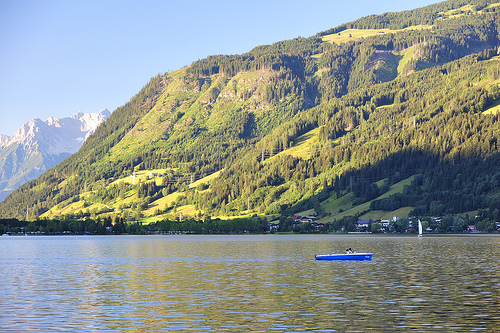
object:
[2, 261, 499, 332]
water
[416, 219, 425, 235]
sail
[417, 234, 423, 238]
boat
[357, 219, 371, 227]
house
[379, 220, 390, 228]
house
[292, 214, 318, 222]
house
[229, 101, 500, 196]
mountain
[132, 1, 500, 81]
mountain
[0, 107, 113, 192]
mountain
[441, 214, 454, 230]
tree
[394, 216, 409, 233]
tree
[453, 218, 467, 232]
tree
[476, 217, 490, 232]
tree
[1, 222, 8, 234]
tree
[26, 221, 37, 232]
tree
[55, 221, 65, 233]
tree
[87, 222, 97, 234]
tree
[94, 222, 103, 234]
tree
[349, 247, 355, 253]
person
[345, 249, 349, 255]
person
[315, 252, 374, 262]
boat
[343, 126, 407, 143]
wires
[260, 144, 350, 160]
wires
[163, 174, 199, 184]
wires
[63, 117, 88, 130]
snow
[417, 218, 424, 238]
sailboat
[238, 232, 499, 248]
water edge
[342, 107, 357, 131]
tree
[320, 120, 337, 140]
tree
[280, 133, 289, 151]
tree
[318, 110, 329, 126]
tree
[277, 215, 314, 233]
trees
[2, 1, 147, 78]
sky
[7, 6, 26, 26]
clouds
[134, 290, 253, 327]
ripples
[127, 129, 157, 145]
grass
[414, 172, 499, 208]
shadow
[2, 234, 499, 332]
lake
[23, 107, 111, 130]
mountain top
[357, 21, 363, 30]
green tree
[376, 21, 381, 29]
green tree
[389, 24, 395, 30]
green tree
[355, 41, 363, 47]
green tree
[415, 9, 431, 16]
trees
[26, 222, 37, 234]
green tree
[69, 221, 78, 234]
green tree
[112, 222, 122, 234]
green tree